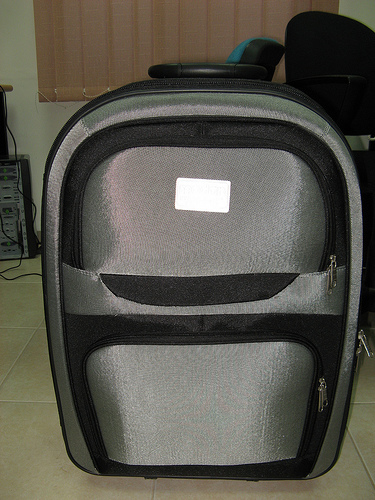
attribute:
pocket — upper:
[59, 113, 352, 316]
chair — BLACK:
[282, 8, 373, 153]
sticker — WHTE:
[172, 173, 233, 216]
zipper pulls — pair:
[323, 249, 342, 293]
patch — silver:
[89, 338, 303, 445]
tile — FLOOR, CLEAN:
[7, 306, 39, 449]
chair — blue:
[222, 37, 294, 81]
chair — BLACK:
[272, 3, 373, 144]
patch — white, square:
[174, 175, 231, 214]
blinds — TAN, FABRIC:
[31, 2, 336, 102]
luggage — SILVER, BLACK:
[43, 47, 346, 499]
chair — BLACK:
[257, 9, 373, 141]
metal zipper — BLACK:
[319, 244, 354, 297]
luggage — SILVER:
[32, 109, 318, 492]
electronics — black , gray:
[1, 153, 37, 261]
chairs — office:
[135, 5, 373, 145]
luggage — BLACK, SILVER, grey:
[17, 52, 366, 484]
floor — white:
[3, 250, 373, 498]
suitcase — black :
[39, 91, 365, 478]